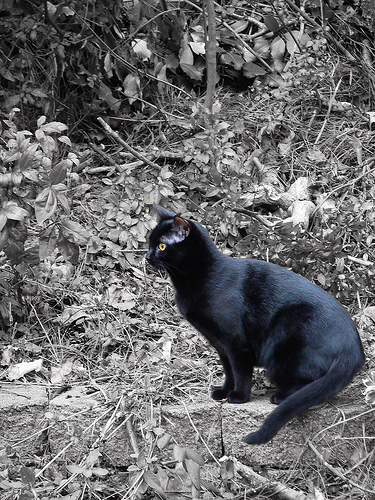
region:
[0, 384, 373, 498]
Stone wall the cat is sitting on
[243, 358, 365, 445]
Cat's long black tail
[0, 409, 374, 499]
Branches and leaves hanging over the stone wall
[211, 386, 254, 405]
Cat's two front paws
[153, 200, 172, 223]
Cat's right ear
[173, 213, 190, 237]
Cat's left ear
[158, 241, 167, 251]
Cat's yellow eye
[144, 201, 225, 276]
Cat's entire head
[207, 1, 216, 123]
Thin tree trunk standing in the background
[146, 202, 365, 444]
Entire black cat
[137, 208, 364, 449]
black cat sitting on rock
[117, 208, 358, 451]
black cat with yellow eyes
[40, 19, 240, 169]
trees, leaves and shrubs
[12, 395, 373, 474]
three cement stones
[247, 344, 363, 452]
long black tail of cat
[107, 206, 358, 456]
cat looking to the left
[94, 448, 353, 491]
twigs and leaves in front of stone bricks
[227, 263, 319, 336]
shiny black cat fur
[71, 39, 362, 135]
photo in black and white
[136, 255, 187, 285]
white whiskers on cats face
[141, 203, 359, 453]
a cat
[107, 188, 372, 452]
a black cat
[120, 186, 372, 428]
a black cat with yellow eyes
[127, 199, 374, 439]
a cat sits on a stone edgeing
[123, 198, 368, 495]
the cat looks at something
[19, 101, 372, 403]
leaves are all over the ground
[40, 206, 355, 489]
a cat sitting on a wall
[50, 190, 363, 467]
the cat has yellow eyes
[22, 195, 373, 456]
a cat looks intently at something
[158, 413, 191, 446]
part of a brick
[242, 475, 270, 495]
part of a branch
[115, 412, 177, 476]
part of some leaves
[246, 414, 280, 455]
part of a tail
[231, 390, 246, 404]
left paw of a cat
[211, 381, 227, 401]
right paw of a cat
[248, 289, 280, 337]
stomach of a cat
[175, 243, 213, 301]
neck of a cat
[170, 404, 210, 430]
edge of a brick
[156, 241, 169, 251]
left eye of a cat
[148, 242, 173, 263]
Cat has yellow eye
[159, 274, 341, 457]
Black cat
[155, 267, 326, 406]
Cat has shiny fur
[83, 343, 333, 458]
Cat sitting on concrete brick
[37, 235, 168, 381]
Leaves laying on the ground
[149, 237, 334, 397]
Cat sitting on ledge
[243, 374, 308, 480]
Cat has black tail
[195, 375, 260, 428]
Cat has black paws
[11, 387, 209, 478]
Concrete bricks in ground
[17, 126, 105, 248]
plants in the background